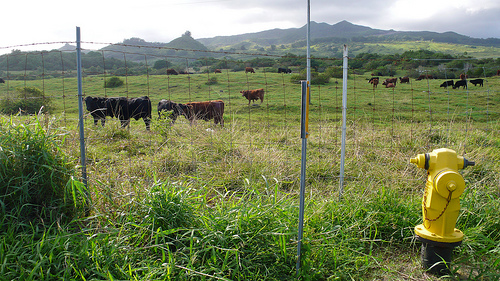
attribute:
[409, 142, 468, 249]
hydrant — yellow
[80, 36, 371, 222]
fence — metal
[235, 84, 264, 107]
cow — brown, standing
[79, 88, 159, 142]
cows — black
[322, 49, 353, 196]
pole — white, metal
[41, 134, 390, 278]
grass — tall, green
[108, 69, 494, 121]
cows — grazing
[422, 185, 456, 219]
chain — brown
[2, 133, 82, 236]
bushes — green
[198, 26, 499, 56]
mountains — in background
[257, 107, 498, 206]
grass — yellow